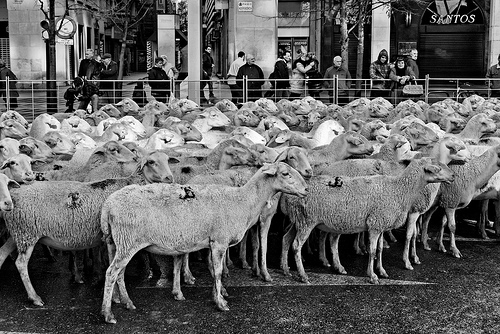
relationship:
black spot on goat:
[83, 175, 121, 191] [12, 151, 172, 259]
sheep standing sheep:
[303, 172, 434, 221] [105, 165, 285, 261]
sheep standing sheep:
[303, 172, 434, 221] [110, 115, 167, 135]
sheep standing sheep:
[303, 172, 434, 221] [278, 98, 330, 121]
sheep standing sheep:
[303, 172, 434, 221] [27, 182, 86, 243]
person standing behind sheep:
[146, 54, 173, 103] [48, 114, 340, 308]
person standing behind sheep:
[362, 45, 392, 89] [314, 83, 452, 217]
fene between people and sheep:
[9, 51, 495, 116] [46, 107, 322, 314]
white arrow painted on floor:
[178, 262, 437, 302] [3, 201, 498, 330]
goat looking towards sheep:
[0, 151, 172, 307] [280, 153, 457, 284]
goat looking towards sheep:
[0, 151, 172, 307] [101, 160, 309, 322]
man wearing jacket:
[234, 52, 265, 107] [225, 70, 261, 95]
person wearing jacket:
[392, 57, 413, 73] [223, 63, 279, 104]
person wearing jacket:
[407, 42, 422, 54] [223, 63, 279, 104]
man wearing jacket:
[234, 53, 265, 109] [223, 63, 279, 104]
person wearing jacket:
[151, 55, 172, 83] [223, 63, 279, 104]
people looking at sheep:
[222, 45, 352, 95] [1, 93, 498, 322]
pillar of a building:
[187, 0, 203, 107] [28, 3, 395, 86]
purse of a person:
[401, 79, 426, 96] [387, 57, 416, 85]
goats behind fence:
[2, 77, 498, 331] [0, 75, 447, 110]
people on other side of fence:
[51, 42, 433, 106] [5, 72, 499, 117]